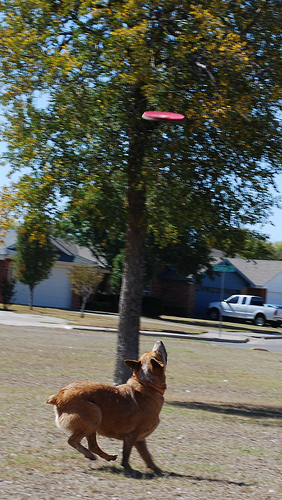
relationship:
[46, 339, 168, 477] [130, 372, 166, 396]
dog has collar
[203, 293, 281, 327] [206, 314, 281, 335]
truck in driveway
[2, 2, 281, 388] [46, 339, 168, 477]
tree near dog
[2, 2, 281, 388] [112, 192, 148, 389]
tree has trunk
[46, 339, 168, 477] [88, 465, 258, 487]
dog has shadow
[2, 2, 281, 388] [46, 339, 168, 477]
tree next to dog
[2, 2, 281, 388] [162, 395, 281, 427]
tree has shadow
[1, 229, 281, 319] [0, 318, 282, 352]
houses across street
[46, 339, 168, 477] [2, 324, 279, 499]
dog on field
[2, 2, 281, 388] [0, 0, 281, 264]
tree has leaves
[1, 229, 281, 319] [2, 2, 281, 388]
houses behind tree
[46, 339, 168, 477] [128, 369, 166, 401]
dog has neck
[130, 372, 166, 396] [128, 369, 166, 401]
collar around neck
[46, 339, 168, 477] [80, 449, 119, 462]
dog has back feet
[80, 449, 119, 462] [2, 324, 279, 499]
back feet off field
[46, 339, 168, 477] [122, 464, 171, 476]
dog has front feet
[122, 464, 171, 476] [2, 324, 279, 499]
front feet on field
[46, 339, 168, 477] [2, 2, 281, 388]
dog in front of tree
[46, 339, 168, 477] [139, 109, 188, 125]
dog watching frisbee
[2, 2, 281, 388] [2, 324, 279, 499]
tree in field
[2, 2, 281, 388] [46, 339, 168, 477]
tree behind dog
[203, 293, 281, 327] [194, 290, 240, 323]
truck before door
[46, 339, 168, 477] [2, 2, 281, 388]
dog next to tree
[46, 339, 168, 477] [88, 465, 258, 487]
dog casts shadow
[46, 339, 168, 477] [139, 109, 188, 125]
dog looking at frisbee